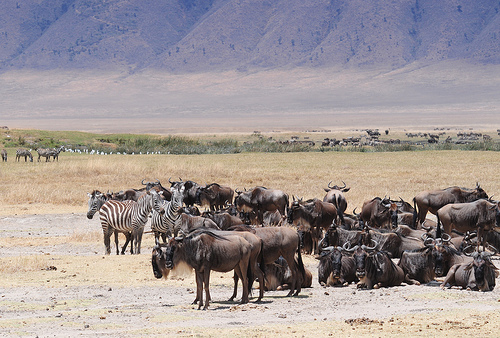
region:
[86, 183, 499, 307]
Animals relaxing on the pasture.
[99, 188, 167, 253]
A zebra.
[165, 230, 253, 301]
A yak.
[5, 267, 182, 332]
Dry grasslands.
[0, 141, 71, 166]
Animals finding something to eat.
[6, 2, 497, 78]
Mountains make the back drop.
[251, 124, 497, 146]
Animals graze in the pasture.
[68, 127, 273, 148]
Grass and brush separate the pastures.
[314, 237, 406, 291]
Yak's sit and relax.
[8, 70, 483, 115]
Deserted landscape.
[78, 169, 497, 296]
a group of animals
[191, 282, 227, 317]
legs of the sheep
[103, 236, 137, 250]
legs of the zebra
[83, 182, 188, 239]
a group of zebra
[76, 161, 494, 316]
zebras and sheeps in ground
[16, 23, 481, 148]
a beautiful view of mountain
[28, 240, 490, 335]
a clear view of sand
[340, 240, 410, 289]
wildebeest in open field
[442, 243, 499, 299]
wildebeest in open field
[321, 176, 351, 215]
wildebeest in open field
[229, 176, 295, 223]
wildebeest in open field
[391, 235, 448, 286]
wildebeest in open field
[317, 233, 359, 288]
wildebeest in open field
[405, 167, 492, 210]
wildebeest in open field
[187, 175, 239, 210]
wildebeest in open field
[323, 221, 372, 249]
wildebeest in open field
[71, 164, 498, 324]
a herd of animals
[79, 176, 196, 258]
several black and white zebras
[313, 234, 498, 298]
animals laying on the dirt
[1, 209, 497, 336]
dirt on the ground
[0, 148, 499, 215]
yellow grass on the ground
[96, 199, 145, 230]
black and white stripes on the body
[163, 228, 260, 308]
side profile of a brown animal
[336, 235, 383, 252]
horns on the head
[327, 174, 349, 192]
horns are curved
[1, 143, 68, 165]
animals standing in the grass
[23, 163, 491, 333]
The animals are out in the wild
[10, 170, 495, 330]
The animals are zebras and wildebeests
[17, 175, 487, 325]
The animals are getting along well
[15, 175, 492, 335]
The animals are watching for danger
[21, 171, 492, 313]
The animals are protecting each other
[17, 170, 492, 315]
Some animals are standing in the dirt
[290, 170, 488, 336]
Some animals are laying down in the dirt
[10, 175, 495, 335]
Some animals are male and female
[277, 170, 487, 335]
The animals have very sharp horns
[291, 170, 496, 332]
The animals use their horns to fight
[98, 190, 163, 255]
a zebra in a field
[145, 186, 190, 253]
a zebra in a field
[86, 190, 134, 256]
a zebra in a field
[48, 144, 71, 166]
a zebra in a field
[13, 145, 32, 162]
a zebra in a field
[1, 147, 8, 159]
a zebra in a field